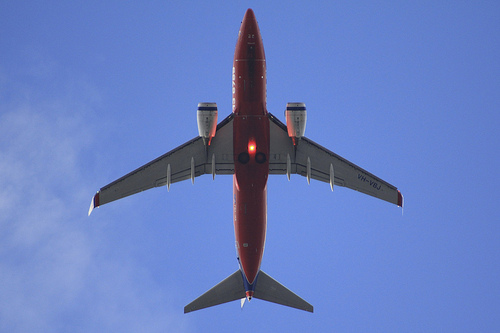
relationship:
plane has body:
[87, 7, 409, 315] [232, 9, 269, 280]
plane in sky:
[87, 7, 409, 315] [2, 2, 499, 332]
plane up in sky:
[87, 7, 409, 315] [2, 2, 499, 332]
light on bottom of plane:
[245, 134, 260, 163] [87, 7, 409, 315]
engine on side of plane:
[284, 98, 310, 153] [87, 7, 409, 315]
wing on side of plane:
[84, 114, 235, 215] [87, 7, 409, 315]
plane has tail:
[87, 7, 409, 315] [182, 262, 317, 319]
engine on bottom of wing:
[193, 98, 222, 153] [84, 114, 235, 215]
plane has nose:
[87, 7, 409, 315] [234, 7, 265, 45]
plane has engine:
[87, 7, 409, 315] [284, 98, 310, 153]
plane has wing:
[87, 7, 409, 315] [84, 114, 235, 215]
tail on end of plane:
[182, 262, 317, 319] [87, 7, 409, 315]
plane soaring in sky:
[87, 7, 409, 315] [2, 2, 499, 332]